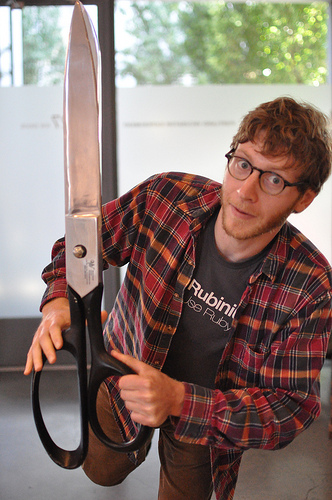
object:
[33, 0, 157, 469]
scissors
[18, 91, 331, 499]
dude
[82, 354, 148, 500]
pants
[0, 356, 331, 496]
floor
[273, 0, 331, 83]
tree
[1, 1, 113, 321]
window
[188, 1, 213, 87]
tree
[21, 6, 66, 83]
tree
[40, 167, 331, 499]
shirt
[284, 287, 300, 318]
plaid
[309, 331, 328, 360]
red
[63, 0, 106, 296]
blades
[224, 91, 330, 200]
hair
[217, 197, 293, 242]
beard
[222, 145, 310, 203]
frames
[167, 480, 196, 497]
brown bottoms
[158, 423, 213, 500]
wrinkles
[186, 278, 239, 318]
'rubinius'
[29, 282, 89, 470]
handle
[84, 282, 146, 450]
handle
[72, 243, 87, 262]
screw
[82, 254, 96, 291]
writing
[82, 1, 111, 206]
bottom blade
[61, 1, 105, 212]
top blade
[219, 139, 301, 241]
face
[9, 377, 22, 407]
shadow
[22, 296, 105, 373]
hand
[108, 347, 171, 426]
hand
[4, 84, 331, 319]
wall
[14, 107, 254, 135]
writing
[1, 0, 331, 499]
gallery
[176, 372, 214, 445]
cuff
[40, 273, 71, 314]
cuff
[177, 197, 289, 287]
collar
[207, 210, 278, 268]
collar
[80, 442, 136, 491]
knee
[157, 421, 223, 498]
leg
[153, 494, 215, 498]
knee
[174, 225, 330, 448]
sleeve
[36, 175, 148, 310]
sleeve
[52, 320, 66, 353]
fingers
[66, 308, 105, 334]
thumb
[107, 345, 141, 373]
thumb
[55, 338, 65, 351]
fingernails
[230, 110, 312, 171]
bangs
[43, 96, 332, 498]
'turkerworkers